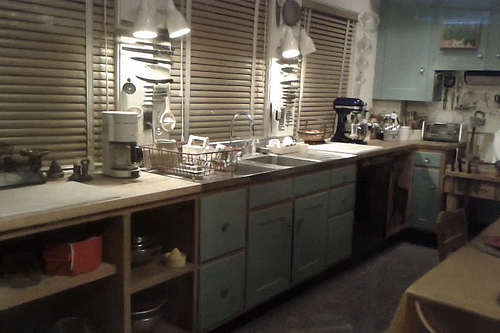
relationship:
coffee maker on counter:
[98, 106, 155, 182] [3, 161, 191, 219]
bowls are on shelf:
[129, 229, 172, 332] [129, 206, 200, 332]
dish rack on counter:
[141, 128, 237, 180] [3, 161, 191, 219]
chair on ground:
[428, 203, 476, 260] [236, 229, 449, 332]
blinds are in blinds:
[2, 1, 360, 134] [0, 0, 358, 170]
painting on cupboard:
[436, 11, 489, 55] [377, 1, 498, 116]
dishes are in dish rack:
[154, 133, 212, 162] [141, 128, 237, 180]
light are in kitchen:
[133, 0, 317, 58] [1, 1, 500, 331]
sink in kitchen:
[228, 138, 318, 187] [1, 1, 500, 331]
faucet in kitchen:
[225, 110, 256, 155] [1, 1, 500, 331]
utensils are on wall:
[436, 72, 498, 116] [379, 75, 499, 156]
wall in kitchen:
[379, 75, 499, 156] [1, 1, 500, 331]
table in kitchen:
[406, 214, 500, 329] [1, 1, 500, 331]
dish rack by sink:
[141, 128, 237, 180] [228, 138, 318, 187]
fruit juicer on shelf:
[157, 242, 193, 270] [129, 206, 200, 332]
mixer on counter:
[328, 91, 369, 150] [302, 121, 424, 160]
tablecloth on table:
[384, 224, 499, 332] [406, 214, 500, 329]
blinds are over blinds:
[2, 1, 360, 134] [0, 0, 358, 170]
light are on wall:
[133, 0, 317, 58] [0, 2, 425, 179]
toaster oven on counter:
[416, 116, 466, 147] [302, 121, 424, 160]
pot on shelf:
[45, 236, 111, 278] [1, 208, 128, 332]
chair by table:
[428, 203, 476, 260] [406, 214, 500, 329]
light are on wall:
[133, 0, 317, 58] [379, 75, 499, 156]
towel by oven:
[392, 151, 418, 211] [355, 157, 396, 260]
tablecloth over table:
[384, 224, 499, 332] [406, 214, 500, 329]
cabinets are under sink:
[199, 166, 368, 323] [228, 138, 318, 187]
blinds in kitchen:
[0, 0, 358, 170] [1, 1, 500, 331]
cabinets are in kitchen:
[199, 166, 368, 323] [1, 1, 500, 331]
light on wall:
[133, 7, 319, 75] [0, 2, 425, 179]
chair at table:
[428, 203, 476, 260] [406, 214, 500, 329]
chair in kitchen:
[428, 203, 476, 260] [1, 1, 500, 331]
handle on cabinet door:
[290, 207, 313, 229] [291, 197, 331, 282]